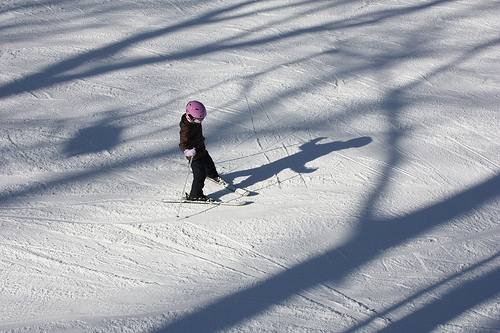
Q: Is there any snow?
A: Yes, there is snow.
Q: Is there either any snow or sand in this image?
A: Yes, there is snow.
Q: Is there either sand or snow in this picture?
A: Yes, there is snow.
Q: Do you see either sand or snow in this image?
A: Yes, there is snow.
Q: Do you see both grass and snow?
A: No, there is snow but no grass.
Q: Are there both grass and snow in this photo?
A: No, there is snow but no grass.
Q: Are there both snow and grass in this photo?
A: No, there is snow but no grass.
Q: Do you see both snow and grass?
A: No, there is snow but no grass.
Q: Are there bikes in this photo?
A: No, there are no bikes.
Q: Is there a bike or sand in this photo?
A: No, there are no bikes or sand.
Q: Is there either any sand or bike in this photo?
A: No, there are no bikes or sand.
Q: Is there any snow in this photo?
A: Yes, there is snow.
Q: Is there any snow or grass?
A: Yes, there is snow.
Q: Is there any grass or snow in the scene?
A: Yes, there is snow.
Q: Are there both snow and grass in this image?
A: No, there is snow but no grass.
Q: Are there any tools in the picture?
A: No, there are no tools.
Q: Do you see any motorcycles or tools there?
A: No, there are no tools or motorcycles.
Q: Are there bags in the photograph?
A: No, there are no bags.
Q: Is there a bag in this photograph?
A: No, there are no bags.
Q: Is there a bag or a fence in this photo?
A: No, there are no bags or fences.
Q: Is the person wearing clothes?
A: Yes, the person is wearing clothes.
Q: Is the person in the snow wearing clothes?
A: Yes, the person is wearing clothes.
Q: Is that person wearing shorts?
A: No, the person is wearing clothes.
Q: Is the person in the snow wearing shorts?
A: No, the person is wearing clothes.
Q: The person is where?
A: The person is in the snow.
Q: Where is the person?
A: The person is in the snow.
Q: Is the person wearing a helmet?
A: Yes, the person is wearing a helmet.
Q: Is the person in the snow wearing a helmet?
A: Yes, the person is wearing a helmet.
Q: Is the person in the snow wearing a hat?
A: No, the person is wearing a helmet.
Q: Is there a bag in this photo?
A: No, there are no bags.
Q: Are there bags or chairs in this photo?
A: No, there are no bags or chairs.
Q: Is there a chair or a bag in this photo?
A: No, there are no bags or chairs.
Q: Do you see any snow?
A: Yes, there is snow.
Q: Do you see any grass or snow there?
A: Yes, there is snow.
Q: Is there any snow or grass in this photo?
A: Yes, there is snow.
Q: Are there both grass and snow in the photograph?
A: No, there is snow but no grass.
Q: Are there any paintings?
A: No, there are no paintings.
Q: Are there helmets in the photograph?
A: Yes, there is a helmet.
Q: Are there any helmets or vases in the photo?
A: Yes, there is a helmet.